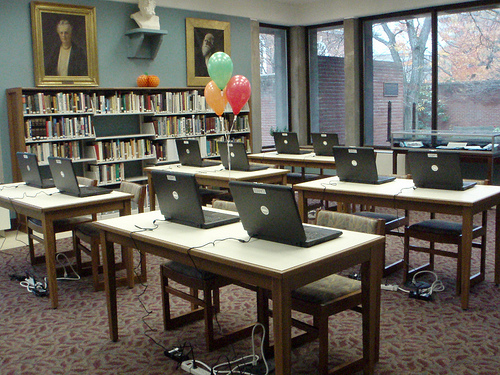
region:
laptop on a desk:
[227, 175, 337, 250]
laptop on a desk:
[145, 158, 215, 248]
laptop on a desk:
[42, 150, 108, 201]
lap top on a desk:
[5, 145, 41, 188]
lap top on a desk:
[393, 145, 483, 190]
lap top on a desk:
[322, 146, 387, 188]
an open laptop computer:
[225, 178, 339, 247]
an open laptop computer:
[150, 168, 237, 229]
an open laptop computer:
[47, 153, 111, 196]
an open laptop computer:
[14, 150, 53, 190]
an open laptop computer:
[173, 138, 218, 168]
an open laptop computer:
[215, 139, 266, 173]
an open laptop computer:
[331, 145, 395, 185]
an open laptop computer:
[404, 146, 475, 191]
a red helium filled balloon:
[226, 76, 250, 116]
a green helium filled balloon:
[205, 51, 235, 92]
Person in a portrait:
[45, 14, 86, 71]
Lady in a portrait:
[45, 15, 87, 74]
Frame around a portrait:
[25, 3, 102, 91]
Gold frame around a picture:
[29, 3, 97, 89]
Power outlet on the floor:
[179, 355, 207, 371]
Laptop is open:
[227, 173, 343, 248]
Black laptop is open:
[227, 170, 346, 246]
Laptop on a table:
[226, 175, 348, 270]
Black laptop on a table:
[225, 168, 360, 278]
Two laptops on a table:
[145, 155, 350, 265]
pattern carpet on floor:
[26, 320, 93, 360]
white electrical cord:
[241, 318, 284, 356]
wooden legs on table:
[335, 255, 408, 334]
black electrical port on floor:
[153, 340, 190, 362]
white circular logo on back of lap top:
[250, 195, 275, 221]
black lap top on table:
[139, 145, 227, 242]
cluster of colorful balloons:
[171, 51, 269, 155]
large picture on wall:
[31, 2, 113, 90]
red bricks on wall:
[321, 51, 421, 151]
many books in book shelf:
[16, 80, 243, 187]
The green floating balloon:
[205, 50, 230, 91]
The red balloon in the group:
[225, 75, 250, 115]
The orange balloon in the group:
[200, 80, 225, 115]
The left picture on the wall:
[30, 0, 95, 82]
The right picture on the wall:
[185, 17, 230, 82]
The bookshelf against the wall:
[5, 85, 255, 235]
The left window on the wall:
[257, 20, 288, 146]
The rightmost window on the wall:
[435, 5, 495, 150]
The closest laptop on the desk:
[225, 180, 340, 241]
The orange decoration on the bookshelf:
[135, 70, 160, 85]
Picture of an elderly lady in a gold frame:
[33, 3, 100, 88]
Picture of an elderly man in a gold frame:
[188, 16, 233, 89]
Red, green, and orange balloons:
[203, 52, 250, 117]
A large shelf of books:
[5, 88, 255, 181]